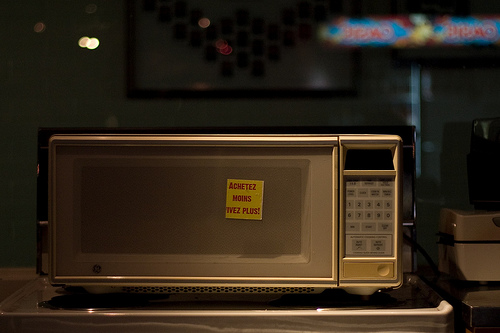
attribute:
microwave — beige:
[46, 116, 413, 306]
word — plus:
[223, 174, 270, 196]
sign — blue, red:
[329, 12, 496, 47]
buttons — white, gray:
[341, 175, 396, 257]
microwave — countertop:
[40, 125, 407, 297]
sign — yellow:
[224, 178, 265, 222]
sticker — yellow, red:
[224, 177, 262, 221]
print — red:
[224, 175, 262, 220]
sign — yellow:
[222, 176, 269, 223]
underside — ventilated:
[44, 276, 360, 310]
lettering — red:
[222, 174, 268, 225]